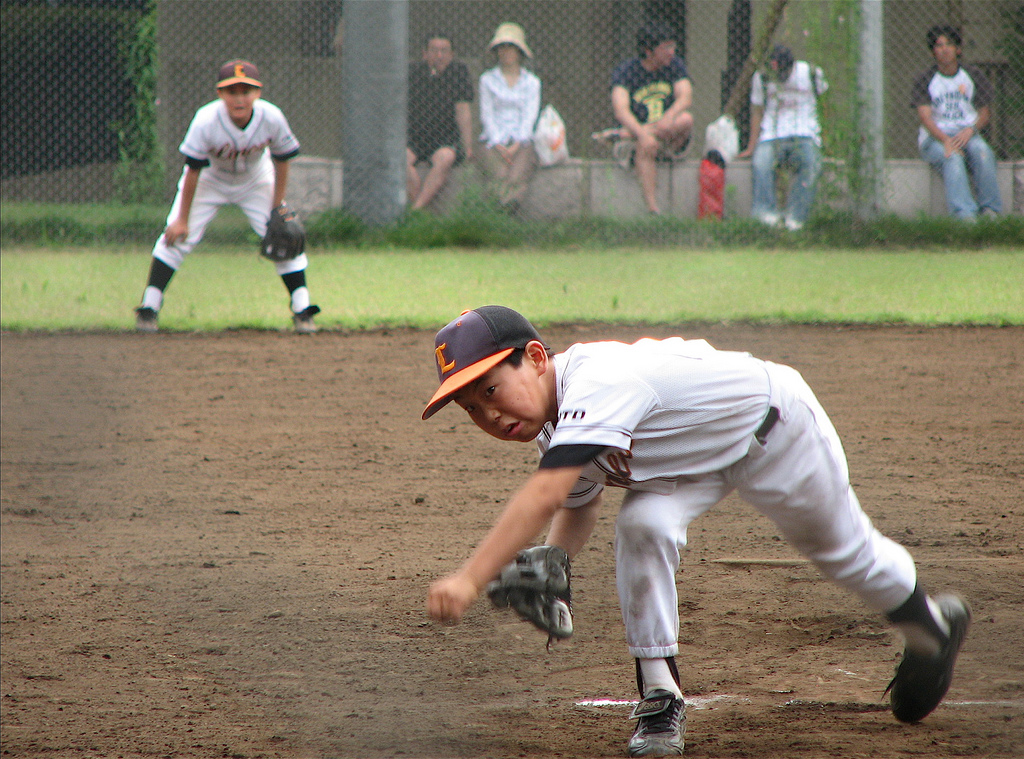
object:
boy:
[376, 281, 1021, 755]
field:
[0, 232, 1019, 757]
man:
[914, 18, 1015, 231]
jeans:
[918, 117, 1020, 228]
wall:
[225, 142, 1024, 265]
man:
[734, 35, 838, 244]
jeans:
[743, 130, 832, 234]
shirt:
[471, 64, 548, 150]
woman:
[452, 0, 561, 247]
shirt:
[397, 62, 477, 156]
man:
[383, 20, 484, 233]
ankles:
[403, 198, 429, 216]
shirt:
[743, 61, 831, 148]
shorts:
[402, 130, 470, 165]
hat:
[413, 301, 557, 421]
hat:
[213, 55, 267, 94]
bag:
[529, 102, 572, 173]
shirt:
[903, 62, 998, 145]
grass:
[2, 219, 1020, 331]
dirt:
[2, 327, 1021, 756]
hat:
[481, 15, 542, 63]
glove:
[477, 539, 584, 644]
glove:
[249, 200, 322, 268]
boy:
[116, 42, 345, 348]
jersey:
[540, 324, 785, 516]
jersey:
[169, 100, 313, 203]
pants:
[140, 158, 320, 286]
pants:
[604, 356, 937, 686]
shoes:
[865, 581, 993, 737]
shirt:
[606, 57, 693, 143]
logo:
[629, 78, 681, 127]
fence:
[3, 5, 1024, 261]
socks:
[275, 264, 320, 319]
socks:
[629, 646, 696, 705]